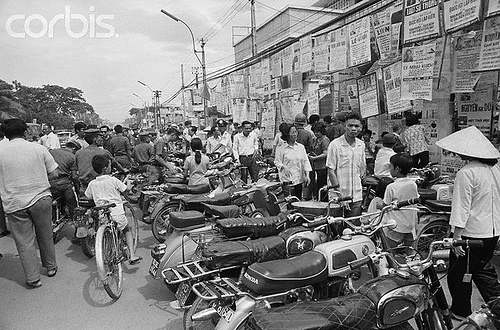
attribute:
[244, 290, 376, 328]
seat — leather, smooth, piped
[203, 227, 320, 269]
seat — black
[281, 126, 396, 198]
boy — thin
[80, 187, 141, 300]
bicycle — chrome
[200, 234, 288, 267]
seat — black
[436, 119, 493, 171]
hat — white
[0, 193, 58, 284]
pants — grey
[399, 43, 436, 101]
flyer — flapping, blowing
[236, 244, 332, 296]
seat — black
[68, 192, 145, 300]
bicycle — chrome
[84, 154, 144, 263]
boy — little, young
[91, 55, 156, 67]
clouds — white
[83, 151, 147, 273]
boy — little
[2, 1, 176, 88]
sky — cloudy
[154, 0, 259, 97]
wires — electrical 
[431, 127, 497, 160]
hat — chinese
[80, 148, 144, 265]
boy — little